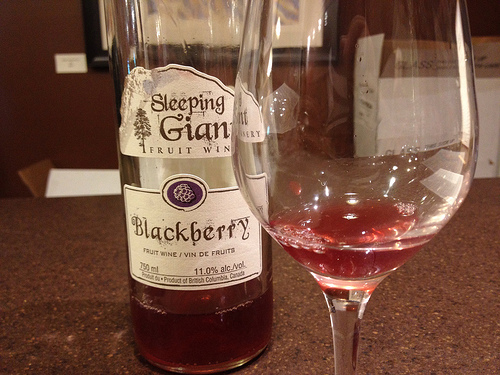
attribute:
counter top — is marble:
[9, 158, 499, 366]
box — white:
[348, 33, 498, 177]